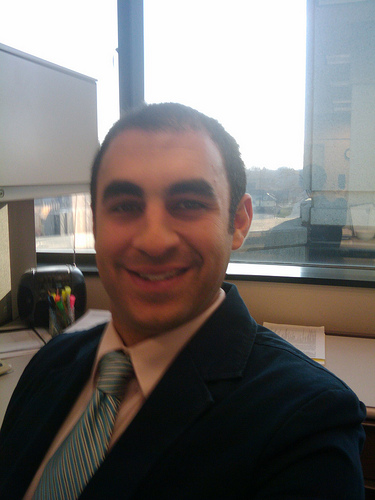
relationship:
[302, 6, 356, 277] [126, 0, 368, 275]
reflection in window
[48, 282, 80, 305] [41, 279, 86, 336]
pens in cup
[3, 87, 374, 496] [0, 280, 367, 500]
man in jacket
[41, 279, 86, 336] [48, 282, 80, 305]
cup of pens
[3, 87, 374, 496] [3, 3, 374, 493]
man in office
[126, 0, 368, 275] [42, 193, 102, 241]
window shows cityscape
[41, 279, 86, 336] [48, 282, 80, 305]
cup with pens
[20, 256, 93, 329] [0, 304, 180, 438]
radio on desk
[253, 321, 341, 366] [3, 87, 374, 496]
paperwork behind man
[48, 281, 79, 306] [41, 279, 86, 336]
highlighters in cup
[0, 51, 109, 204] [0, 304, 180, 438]
cabinet above desk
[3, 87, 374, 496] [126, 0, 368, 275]
man in front of window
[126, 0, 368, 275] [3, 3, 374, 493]
window in office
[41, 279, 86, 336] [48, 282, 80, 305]
cup full of pens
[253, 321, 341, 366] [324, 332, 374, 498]
stack on cabinet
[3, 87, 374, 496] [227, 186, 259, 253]
man has ear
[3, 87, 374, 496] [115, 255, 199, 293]
man has smile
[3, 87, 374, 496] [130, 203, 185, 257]
man has nose